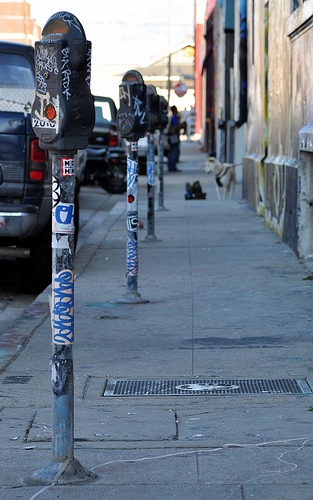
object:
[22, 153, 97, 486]
poles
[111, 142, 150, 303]
poles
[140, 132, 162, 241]
poles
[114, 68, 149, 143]
parking meters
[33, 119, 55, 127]
numbers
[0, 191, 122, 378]
curb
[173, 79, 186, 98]
sign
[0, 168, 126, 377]
roadside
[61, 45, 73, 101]
graffiti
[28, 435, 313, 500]
string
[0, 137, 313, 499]
ground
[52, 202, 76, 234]
sticker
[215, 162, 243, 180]
harness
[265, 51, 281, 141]
graffitti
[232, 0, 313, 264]
wall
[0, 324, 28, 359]
graffiti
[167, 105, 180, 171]
person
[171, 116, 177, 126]
blue shirt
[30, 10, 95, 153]
parking meters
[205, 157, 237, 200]
dog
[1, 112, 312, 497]
street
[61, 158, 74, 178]
letterig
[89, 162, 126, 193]
bag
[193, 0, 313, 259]
building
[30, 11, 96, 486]
meter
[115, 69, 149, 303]
meter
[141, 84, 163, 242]
meter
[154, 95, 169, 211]
meter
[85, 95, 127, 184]
car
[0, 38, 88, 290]
car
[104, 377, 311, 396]
grate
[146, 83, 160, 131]
parking meters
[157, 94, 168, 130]
parking meters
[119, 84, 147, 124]
graffiti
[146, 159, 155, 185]
graffiti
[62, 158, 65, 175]
background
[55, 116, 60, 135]
background